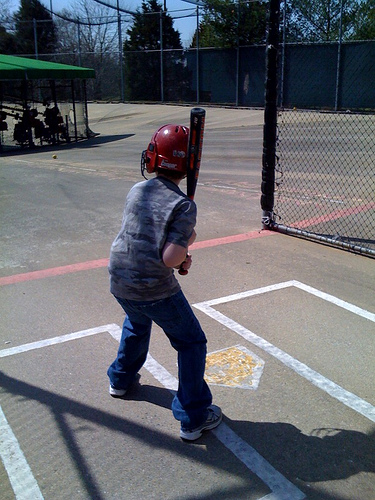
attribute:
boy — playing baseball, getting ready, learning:
[104, 125, 222, 443]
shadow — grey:
[127, 374, 374, 485]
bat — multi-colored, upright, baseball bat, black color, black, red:
[178, 108, 206, 275]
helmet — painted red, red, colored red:
[140, 124, 186, 180]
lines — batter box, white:
[0, 323, 303, 498]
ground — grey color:
[1, 102, 372, 499]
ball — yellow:
[50, 152, 58, 159]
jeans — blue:
[107, 287, 212, 431]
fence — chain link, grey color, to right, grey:
[0, 2, 375, 113]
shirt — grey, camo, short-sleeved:
[107, 179, 196, 303]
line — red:
[1, 204, 366, 285]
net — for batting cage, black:
[259, 3, 374, 262]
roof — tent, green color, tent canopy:
[0, 52, 94, 82]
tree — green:
[125, 0, 184, 103]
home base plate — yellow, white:
[203, 345, 266, 391]